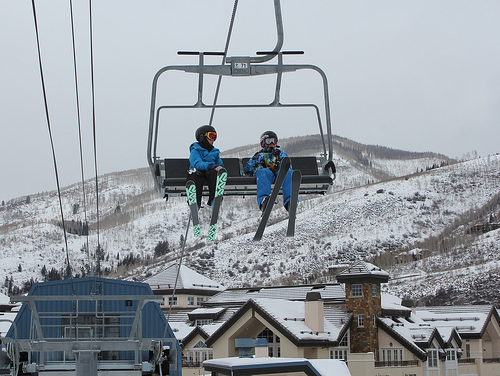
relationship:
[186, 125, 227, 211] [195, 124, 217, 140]
people has a cap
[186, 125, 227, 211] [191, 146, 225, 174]
people has a coat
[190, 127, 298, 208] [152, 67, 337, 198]
people are on a ski lift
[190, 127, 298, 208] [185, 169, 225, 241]
people have skis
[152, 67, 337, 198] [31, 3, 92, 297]
ski lift has a cable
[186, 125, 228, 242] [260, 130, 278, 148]
skier has a helmet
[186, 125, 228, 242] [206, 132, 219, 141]
skier has goggles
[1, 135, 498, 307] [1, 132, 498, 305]
snow on mountain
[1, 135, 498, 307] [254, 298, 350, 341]
snow on roof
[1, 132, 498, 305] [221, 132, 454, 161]
mountain has a top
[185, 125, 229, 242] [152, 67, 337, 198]
skier are on a ski lift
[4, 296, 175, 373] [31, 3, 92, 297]
lift has a cable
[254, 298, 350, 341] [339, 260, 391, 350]
roof has a chimney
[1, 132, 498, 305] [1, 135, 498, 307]
mountain has snow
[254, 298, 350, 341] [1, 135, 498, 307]
roof has snow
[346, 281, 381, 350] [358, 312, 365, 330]
tower has a window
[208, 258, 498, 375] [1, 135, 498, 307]
lodge has snow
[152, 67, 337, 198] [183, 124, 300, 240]
ski lift has kids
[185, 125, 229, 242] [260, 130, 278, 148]
skier have a helmet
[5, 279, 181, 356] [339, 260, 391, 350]
building has a chimney